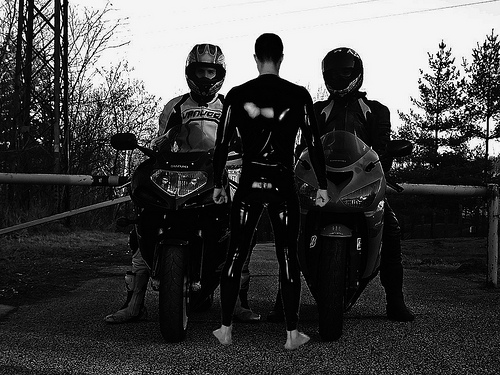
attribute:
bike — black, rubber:
[298, 188, 393, 338]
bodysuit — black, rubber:
[208, 72, 338, 340]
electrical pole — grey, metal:
[10, 1, 82, 223]